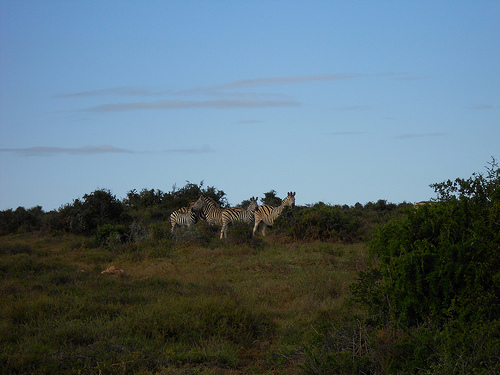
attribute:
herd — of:
[160, 176, 319, 246]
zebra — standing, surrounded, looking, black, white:
[251, 191, 296, 239]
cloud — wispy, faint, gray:
[4, 143, 139, 160]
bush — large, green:
[355, 159, 498, 370]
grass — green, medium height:
[0, 249, 371, 374]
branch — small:
[309, 321, 338, 350]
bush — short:
[275, 202, 366, 243]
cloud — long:
[77, 100, 302, 113]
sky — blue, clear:
[1, 2, 499, 208]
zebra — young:
[218, 196, 260, 243]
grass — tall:
[136, 221, 297, 253]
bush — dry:
[279, 324, 377, 375]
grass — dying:
[102, 243, 227, 282]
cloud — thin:
[321, 128, 369, 137]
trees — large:
[0, 179, 389, 235]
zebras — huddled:
[170, 190, 296, 242]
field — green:
[6, 228, 378, 374]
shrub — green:
[184, 222, 215, 250]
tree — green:
[374, 174, 499, 331]